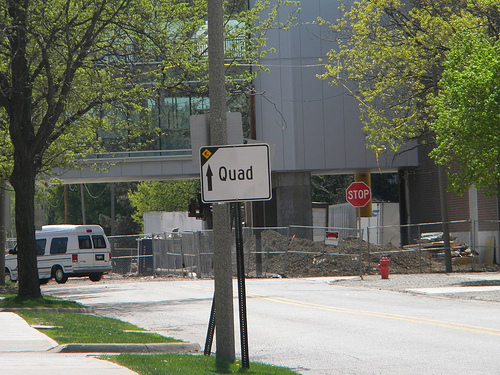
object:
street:
[39, 274, 499, 375]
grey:
[81, 51, 129, 96]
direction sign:
[192, 138, 276, 373]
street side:
[0, 271, 304, 375]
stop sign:
[342, 179, 375, 209]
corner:
[313, 270, 363, 295]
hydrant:
[376, 252, 392, 281]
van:
[2, 222, 117, 290]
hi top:
[35, 224, 104, 232]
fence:
[97, 218, 497, 275]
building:
[0, 0, 432, 256]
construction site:
[70, 177, 497, 283]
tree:
[1, 1, 286, 314]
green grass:
[58, 310, 117, 343]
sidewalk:
[1, 312, 139, 375]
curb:
[51, 341, 205, 355]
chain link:
[110, 235, 184, 278]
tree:
[314, 3, 500, 273]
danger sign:
[322, 229, 341, 247]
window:
[155, 89, 189, 153]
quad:
[217, 163, 255, 183]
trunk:
[15, 187, 42, 306]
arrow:
[205, 162, 215, 193]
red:
[355, 184, 362, 188]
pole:
[201, 1, 239, 375]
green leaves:
[468, 71, 484, 85]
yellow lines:
[242, 295, 498, 340]